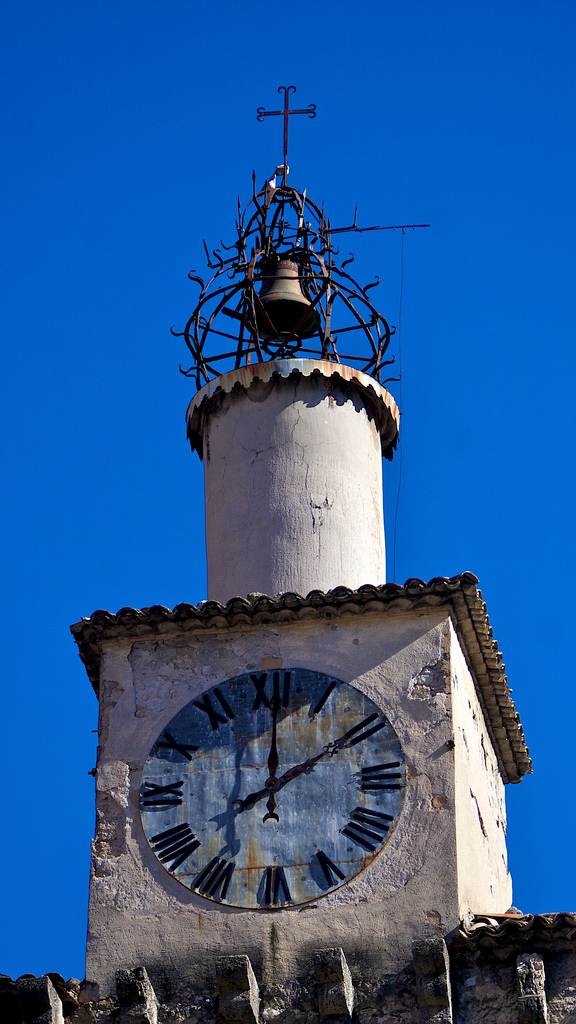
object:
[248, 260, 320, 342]
bell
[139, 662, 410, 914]
clock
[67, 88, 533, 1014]
building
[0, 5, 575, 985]
sky